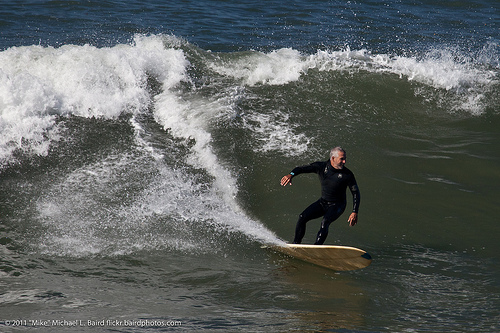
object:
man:
[277, 142, 367, 246]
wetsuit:
[289, 159, 363, 245]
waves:
[4, 30, 488, 232]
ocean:
[2, 0, 250, 333]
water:
[2, 2, 500, 61]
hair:
[329, 143, 345, 153]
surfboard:
[272, 239, 376, 280]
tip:
[360, 249, 375, 262]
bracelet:
[288, 170, 295, 178]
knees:
[296, 210, 307, 221]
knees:
[319, 219, 329, 229]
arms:
[345, 176, 364, 226]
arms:
[279, 159, 320, 190]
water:
[1, 273, 500, 332]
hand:
[278, 172, 293, 187]